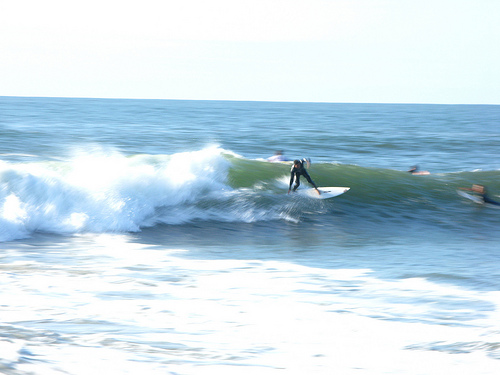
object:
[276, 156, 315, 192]
surfer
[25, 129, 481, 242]
wave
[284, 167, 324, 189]
wetsuit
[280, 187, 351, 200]
surfboard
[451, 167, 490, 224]
surfer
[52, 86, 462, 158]
ocean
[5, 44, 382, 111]
day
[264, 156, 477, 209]
people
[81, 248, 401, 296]
water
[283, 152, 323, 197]
person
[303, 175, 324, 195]
leg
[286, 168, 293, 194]
arm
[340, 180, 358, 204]
tip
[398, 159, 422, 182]
object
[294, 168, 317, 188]
suit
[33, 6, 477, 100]
sky